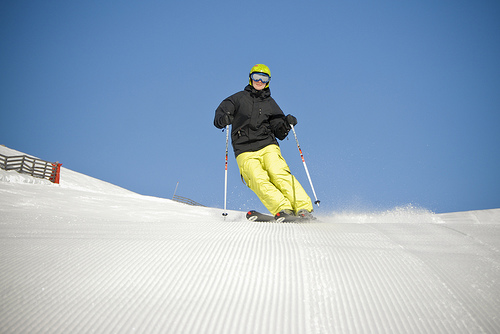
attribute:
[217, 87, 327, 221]
man — skiing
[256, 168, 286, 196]
pants — yellow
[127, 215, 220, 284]
snow — groomed, white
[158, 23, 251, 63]
sky — blue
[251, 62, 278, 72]
helmet — yellow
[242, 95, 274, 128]
jacket — black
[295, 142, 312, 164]
pole — black, white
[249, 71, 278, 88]
goggles — blue